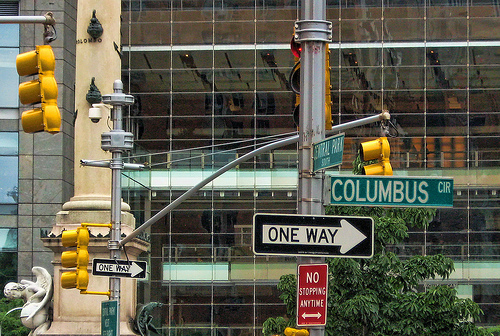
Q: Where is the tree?
A: Behind one way sign.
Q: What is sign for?
A: Columbus.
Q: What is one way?
A: Sign.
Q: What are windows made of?
A: Glass.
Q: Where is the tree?
A: Side of road.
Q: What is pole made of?
A: Metal.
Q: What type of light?
A: Traffic.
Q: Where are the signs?
A: On pole.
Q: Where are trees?
A: Front of building.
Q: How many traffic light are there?
A: 3.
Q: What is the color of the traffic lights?
A: Yellow.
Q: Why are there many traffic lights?
A: It's a junction.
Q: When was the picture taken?
A: During the day.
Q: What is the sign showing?
A: One way.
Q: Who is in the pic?
A: No one.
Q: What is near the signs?
A: A tree.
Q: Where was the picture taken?
A: On Columbus Circle.